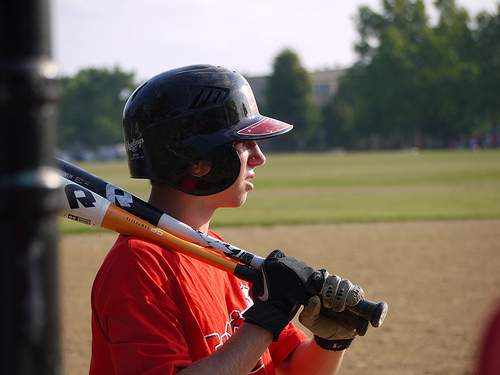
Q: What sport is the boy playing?
A: Baseball.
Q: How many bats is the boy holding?
A: Two.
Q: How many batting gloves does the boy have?
A: Two.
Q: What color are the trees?
A: Green.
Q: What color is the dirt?
A: Brown.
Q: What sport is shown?
A: Baseball.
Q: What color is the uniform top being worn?
A: Orange.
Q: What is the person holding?
A: Baseball bats.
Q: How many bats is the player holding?
A: Two.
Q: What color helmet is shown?
A: Black.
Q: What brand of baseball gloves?
A: Nike.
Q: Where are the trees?
A: Behind the fence.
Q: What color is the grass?
A: Green.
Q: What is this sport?
A: Baseball.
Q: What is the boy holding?
A: Bat.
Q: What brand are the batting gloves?
A: Nike.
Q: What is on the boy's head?
A: Helmet.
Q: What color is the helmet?
A: Black.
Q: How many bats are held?
A: Two.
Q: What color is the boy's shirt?
A: Red.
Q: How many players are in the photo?
A: One.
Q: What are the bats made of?
A: Aluminum.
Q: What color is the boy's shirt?
A: Red.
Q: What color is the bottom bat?
A: Orange.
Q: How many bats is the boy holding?
A: Two.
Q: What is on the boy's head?
A: A helmet.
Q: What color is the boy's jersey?
A: Red.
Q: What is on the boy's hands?
A: Gloves.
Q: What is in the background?
A: Trees.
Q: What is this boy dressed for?
A: A baseball game.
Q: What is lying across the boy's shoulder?
A: Two baseball bats.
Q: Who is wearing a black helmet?
A: A young baseball player.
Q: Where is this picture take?
A: Baseball field.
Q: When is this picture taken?
A: During a baseball game.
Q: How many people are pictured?
A: One.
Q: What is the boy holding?
A: A bat.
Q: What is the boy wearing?
A: A helmet.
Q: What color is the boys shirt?
A: Orange.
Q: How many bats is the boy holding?
A: Two.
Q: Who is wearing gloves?
A: The baseball player.